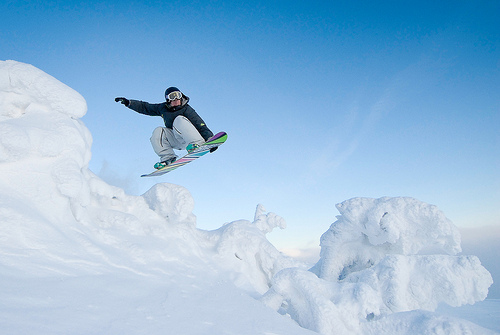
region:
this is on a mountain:
[22, 28, 448, 310]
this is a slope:
[63, 30, 432, 331]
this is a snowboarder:
[44, 61, 269, 251]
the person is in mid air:
[103, 74, 268, 214]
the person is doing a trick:
[140, 83, 279, 190]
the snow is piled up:
[52, 160, 489, 331]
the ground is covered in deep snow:
[15, 156, 141, 251]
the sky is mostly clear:
[198, 18, 468, 168]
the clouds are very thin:
[310, 48, 422, 194]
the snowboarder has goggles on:
[133, 83, 216, 118]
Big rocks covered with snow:
[13, 65, 114, 331]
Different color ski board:
[111, 62, 231, 172]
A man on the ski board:
[116, 85, 217, 172]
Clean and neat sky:
[240, 7, 450, 107]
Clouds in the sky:
[275, 192, 495, 285]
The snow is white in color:
[10, 217, 117, 332]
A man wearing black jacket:
[95, 67, 232, 167]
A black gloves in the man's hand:
[110, 80, 195, 122]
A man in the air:
[96, 70, 249, 213]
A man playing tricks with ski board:
[104, 76, 235, 192]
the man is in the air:
[113, 82, 237, 171]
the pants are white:
[148, 119, 207, 151]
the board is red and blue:
[148, 140, 226, 180]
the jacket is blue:
[128, 97, 215, 125]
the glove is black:
[112, 94, 132, 106]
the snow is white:
[3, 64, 116, 333]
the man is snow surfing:
[102, 77, 244, 195]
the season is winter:
[2, 4, 497, 333]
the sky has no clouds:
[286, 42, 476, 173]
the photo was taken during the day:
[3, 7, 498, 333]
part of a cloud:
[309, 139, 360, 180]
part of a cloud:
[96, 236, 158, 291]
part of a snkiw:
[27, 241, 46, 283]